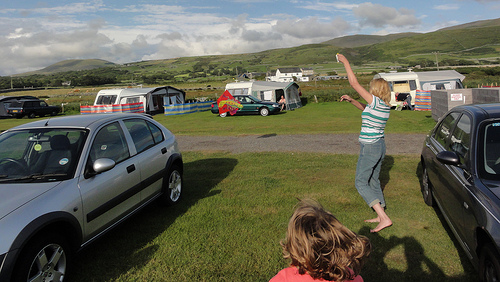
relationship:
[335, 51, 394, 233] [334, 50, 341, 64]
woman holding object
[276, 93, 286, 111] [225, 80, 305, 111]
person sitting in tent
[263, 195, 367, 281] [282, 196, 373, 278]
female with shiny hair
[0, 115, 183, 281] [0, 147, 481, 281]
car parked on grass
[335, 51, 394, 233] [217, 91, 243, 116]
woman directing kite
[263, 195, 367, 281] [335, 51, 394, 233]
child playing with woman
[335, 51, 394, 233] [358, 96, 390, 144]
woman in striped shirt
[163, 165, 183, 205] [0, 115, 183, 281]
tire on silver car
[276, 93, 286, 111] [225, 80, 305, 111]
camper in tent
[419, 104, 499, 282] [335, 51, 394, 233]
car next to woman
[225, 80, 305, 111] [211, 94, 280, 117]
tent behind green car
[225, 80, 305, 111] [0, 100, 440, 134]
camping tents on grass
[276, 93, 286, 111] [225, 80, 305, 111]
man sitting in tent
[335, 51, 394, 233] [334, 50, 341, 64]
woman holding cup